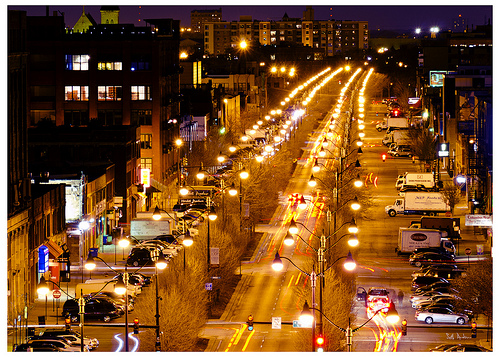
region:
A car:
[409, 263, 462, 345]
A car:
[402, 291, 437, 353]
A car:
[403, 229, 475, 300]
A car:
[429, 257, 476, 352]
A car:
[446, 225, 484, 336]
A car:
[374, 283, 481, 322]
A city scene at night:
[31, 25, 463, 337]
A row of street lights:
[277, 140, 374, 327]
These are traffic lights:
[57, 313, 144, 336]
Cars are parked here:
[405, 245, 472, 330]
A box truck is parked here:
[384, 189, 451, 219]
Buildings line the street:
[34, 27, 256, 302]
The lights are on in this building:
[61, 53, 154, 105]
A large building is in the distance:
[200, 17, 375, 69]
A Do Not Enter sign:
[50, 288, 67, 320]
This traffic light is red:
[311, 322, 331, 347]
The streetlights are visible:
[279, 124, 354, 258]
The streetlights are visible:
[214, 91, 327, 347]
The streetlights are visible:
[259, 196, 360, 351]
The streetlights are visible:
[294, 236, 341, 353]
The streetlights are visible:
[299, 204, 367, 329]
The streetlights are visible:
[259, 161, 406, 304]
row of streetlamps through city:
[119, 54, 399, 348]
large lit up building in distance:
[196, 18, 371, 60]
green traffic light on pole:
[229, 307, 279, 343]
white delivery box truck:
[374, 181, 464, 220]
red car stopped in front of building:
[338, 268, 408, 328]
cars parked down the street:
[42, 202, 204, 347]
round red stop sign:
[39, 277, 67, 306]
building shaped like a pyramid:
[67, 10, 96, 41]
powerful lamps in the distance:
[411, 18, 443, 50]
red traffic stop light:
[303, 328, 347, 346]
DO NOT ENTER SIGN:
[51, 287, 61, 299]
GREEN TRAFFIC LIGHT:
[241, 313, 257, 334]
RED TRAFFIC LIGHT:
[131, 316, 139, 333]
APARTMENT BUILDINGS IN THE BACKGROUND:
[190, 8, 372, 63]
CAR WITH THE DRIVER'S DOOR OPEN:
[354, 282, 392, 313]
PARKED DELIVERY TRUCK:
[381, 188, 455, 218]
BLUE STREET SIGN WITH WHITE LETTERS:
[207, 274, 222, 281]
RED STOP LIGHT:
[379, 152, 387, 164]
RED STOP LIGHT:
[314, 335, 326, 346]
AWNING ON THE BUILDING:
[46, 239, 65, 259]